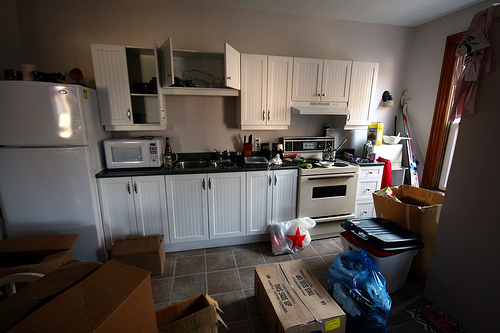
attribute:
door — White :
[269, 55, 291, 128]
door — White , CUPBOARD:
[241, 53, 268, 127]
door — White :
[222, 42, 240, 91]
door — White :
[159, 34, 174, 88]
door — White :
[89, 45, 132, 127]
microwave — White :
[98, 135, 168, 170]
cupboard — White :
[88, 39, 168, 140]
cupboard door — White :
[342, 59, 382, 129]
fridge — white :
[2, 78, 108, 266]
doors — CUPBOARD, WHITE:
[167, 169, 306, 241]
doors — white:
[141, 50, 331, 107]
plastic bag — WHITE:
[265, 213, 320, 258]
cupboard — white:
[125, 178, 294, 248]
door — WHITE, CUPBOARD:
[267, 54, 292, 124]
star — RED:
[289, 226, 307, 256]